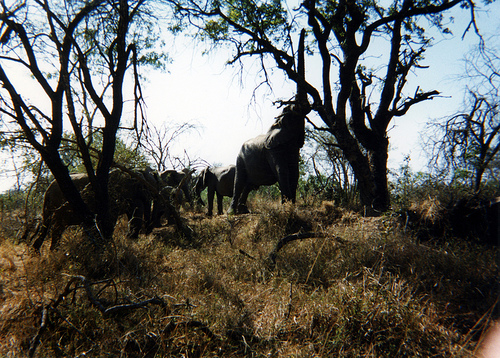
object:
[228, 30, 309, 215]
trunk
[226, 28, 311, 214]
elephant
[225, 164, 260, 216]
leg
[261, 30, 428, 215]
tree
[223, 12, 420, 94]
branch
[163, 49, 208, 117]
sky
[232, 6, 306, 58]
leaves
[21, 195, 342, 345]
tree branches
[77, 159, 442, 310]
ground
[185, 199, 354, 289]
grass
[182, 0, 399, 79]
branches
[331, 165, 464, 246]
bush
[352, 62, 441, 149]
broken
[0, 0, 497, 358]
picture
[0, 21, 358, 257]
elephants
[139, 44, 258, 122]
clouds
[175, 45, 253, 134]
sun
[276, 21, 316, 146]
up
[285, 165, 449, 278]
underbrush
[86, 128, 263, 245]
left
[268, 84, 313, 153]
head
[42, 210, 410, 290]
field